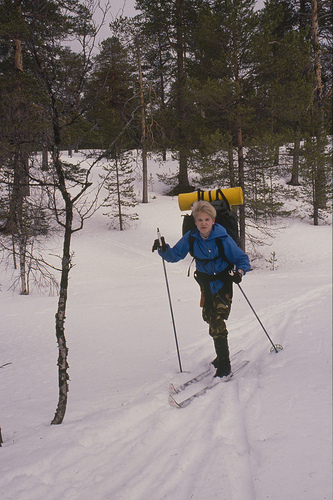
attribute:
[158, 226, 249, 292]
jacket — blue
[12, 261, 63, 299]
branches — tree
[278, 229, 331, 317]
snow — white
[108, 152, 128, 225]
tree — small